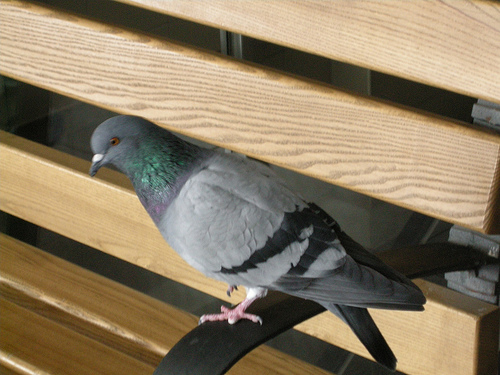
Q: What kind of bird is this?
A: Dove.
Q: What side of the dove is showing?
A: Left.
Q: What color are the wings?
A: Grey and black.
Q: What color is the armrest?
A: Black.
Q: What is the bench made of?
A: Wood.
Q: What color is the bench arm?
A: Black.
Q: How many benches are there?
A: One.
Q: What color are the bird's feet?
A: Pink.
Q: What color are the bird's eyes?
A: Red.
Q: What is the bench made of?
A: Wood.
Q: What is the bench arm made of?
A: Metal.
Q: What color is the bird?
A: Gray.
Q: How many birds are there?
A: One.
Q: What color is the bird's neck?
A: Green.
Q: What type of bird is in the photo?
A: Pigeon.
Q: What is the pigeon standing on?
A: Arm of a bench.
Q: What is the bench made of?
A: Wood and metal.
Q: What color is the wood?
A: Light brown.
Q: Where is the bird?
A: Standing on the bench.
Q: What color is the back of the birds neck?
A: Green.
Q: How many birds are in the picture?
A: 1.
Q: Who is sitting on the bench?
A: No one.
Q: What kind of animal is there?
A: Pigeon.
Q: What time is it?
A: Afternoon.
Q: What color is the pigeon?
A: Gray and black.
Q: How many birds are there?
A: One.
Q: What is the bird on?
A: Bench.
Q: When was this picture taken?
A: Daytime.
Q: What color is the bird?
A: Grey.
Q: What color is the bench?
A: Brown.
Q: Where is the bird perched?
A: On the bench handle.